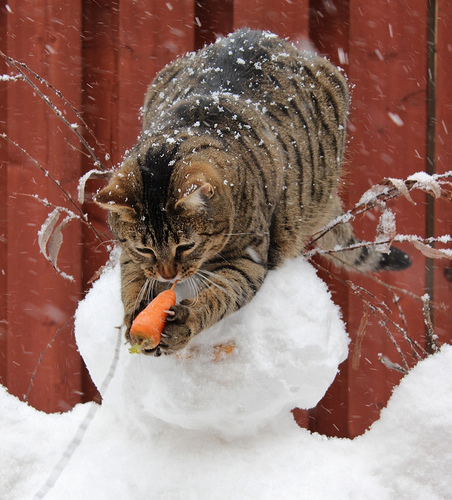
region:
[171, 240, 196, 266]
eye of a cat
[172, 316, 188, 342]
paws of a cat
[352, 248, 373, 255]
tail of a cat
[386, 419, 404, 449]
section of a snow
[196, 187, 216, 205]
ear of a cat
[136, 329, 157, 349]
back part of a carrot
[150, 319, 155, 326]
a carrot on a cat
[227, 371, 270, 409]
section of a snow ball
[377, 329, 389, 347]
a red wall surface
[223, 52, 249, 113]
back of a cat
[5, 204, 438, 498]
a defaced snow man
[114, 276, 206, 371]
a small orange carrot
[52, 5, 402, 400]
a cat on top of a snowman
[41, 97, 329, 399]
a cat eating a carrot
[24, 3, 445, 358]
a cat in the snow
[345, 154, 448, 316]
snow-covered leaves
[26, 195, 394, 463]
the head of a snowman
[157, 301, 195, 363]
a cat's sharp claws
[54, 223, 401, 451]
a snowman with a mouth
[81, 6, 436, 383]
a striped cat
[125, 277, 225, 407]
Cat is holding carrot with 2 front paws.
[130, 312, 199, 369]
Cat's claws are extended.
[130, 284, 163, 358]
Carrot is orange in color.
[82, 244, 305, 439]
Cat is sitting on snowman.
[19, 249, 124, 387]
Wood fence behind cat.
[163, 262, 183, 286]
Cat has brown nose.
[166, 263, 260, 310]
Cat has white whiskers.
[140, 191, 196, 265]
Cat has dark stripes on head.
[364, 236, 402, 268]
Tip of tail is dark.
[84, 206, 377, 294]
Cat is tiger striped.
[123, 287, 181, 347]
The carrot in the cat's paws.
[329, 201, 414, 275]
The tail of the cat.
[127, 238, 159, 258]
The left eye of the cat.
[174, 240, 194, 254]
The right eye of the cat.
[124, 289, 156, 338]
The left paw of the cat.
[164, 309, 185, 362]
The right paw of the cat.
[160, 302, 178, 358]
The nails on the cat's right paw.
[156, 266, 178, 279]
The nose of the cat.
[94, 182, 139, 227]
The left ear of the cat.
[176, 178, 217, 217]
The right ear of the cat.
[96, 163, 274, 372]
Car scores snowman's carrot nose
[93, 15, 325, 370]
Fat cat teeters snowman's head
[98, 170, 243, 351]
Determined cat got wanted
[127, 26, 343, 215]
Cat's coat speckled snow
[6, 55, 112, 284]
Bare branches protrude snowman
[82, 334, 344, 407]
Mouth barely recognizable face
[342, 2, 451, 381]
Wide board fencing background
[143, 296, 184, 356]
Sharp cat claws secure carrot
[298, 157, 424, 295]
Cat tail tip tiger black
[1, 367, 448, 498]
Arms fluffy packed snow